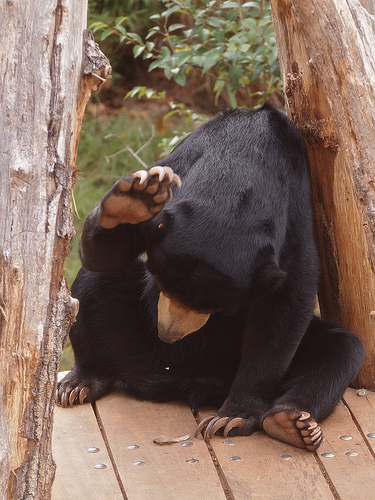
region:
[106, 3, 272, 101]
green leaves on branches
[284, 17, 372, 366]
trunk with worn off bark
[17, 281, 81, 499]
bark on tree trunk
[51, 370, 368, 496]
boards of wood surface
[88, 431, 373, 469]
metal bolts on wood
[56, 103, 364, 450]
sitting bear with head down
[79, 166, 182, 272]
raised paw on bear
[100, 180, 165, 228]
pads on bear paw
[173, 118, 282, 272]
shine on black coat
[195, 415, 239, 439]
claws on bear foot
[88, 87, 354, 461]
this is a bear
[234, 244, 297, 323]
the bear is black in color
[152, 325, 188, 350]
this is the nose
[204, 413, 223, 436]
this is the claws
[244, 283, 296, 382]
this is the leg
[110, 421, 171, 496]
this is a board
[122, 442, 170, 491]
the board is brown in color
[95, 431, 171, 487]
the board is wooden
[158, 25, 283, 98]
this is a tree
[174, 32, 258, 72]
the leaves are green in color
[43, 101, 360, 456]
some type of black animal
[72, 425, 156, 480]
metal studs in a wooden plank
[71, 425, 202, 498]
wooden plank flooring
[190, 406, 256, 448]
claws on the paw of an animal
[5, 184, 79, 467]
a tree trunk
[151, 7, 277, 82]
green leafy plants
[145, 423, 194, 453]
animal food on wooden planks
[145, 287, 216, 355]
the nose of a black animal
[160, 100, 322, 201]
the back of a black animal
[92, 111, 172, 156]
tall green grass on the ground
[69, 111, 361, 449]
a bear sitting on a platform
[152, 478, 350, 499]
brown wood slats of the platform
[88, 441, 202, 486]
grey bolts in the platform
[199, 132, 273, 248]
black fur of the bear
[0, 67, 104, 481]
brown wood support of the platform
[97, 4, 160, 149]
green trees growing behind the bear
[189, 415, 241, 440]
brown claws of the bear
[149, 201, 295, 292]
black furry ears of the bear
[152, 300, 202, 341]
brown nose of the bear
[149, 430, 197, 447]
a small grey animal on the platform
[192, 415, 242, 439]
Claws on a bear's paw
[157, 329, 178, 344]
Black bear's nose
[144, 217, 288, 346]
Black bear looking down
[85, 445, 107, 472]
Nails in a wooden floor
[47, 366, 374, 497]
Wooden platform between two trees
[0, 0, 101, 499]
Tree in front of a black bear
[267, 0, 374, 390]
Black bear leaning against a tree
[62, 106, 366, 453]
Black bear sitting on a wooden platform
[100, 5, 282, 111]
Leaves behind a black bear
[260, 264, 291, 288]
Ear on a black bear